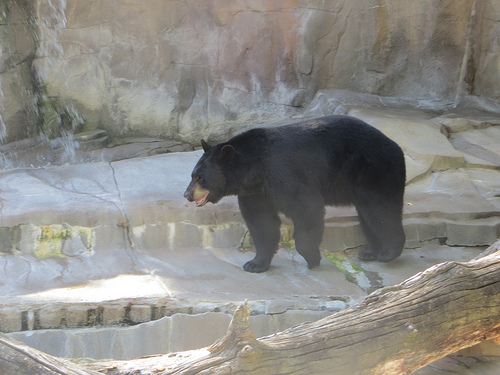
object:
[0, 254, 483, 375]
log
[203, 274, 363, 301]
surface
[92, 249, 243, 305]
surface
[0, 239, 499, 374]
tree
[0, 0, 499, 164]
rock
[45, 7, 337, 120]
crack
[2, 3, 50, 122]
crack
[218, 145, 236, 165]
ear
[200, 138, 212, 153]
ear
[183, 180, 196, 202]
nose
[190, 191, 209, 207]
mouth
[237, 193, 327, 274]
legs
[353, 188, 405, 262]
legs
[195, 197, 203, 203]
tongue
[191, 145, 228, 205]
face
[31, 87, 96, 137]
moss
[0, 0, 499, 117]
wall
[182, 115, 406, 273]
bear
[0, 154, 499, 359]
rock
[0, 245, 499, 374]
branch